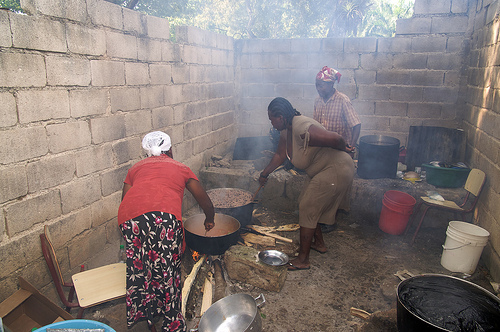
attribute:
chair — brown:
[406, 166, 486, 248]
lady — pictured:
[115, 127, 195, 292]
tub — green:
[414, 160, 476, 188]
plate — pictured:
[262, 249, 290, 269]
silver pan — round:
[259, 245, 290, 266]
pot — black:
[375, 260, 496, 327]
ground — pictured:
[302, 278, 335, 314]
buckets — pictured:
[361, 178, 496, 288]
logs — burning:
[187, 255, 232, 322]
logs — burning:
[223, 222, 297, 292]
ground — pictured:
[290, 266, 352, 326]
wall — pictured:
[53, 28, 120, 190]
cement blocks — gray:
[28, 59, 93, 144]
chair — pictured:
[32, 192, 144, 318]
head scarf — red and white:
[316, 63, 341, 85]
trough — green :
[408, 161, 481, 191]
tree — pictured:
[223, 1, 383, 29]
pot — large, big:
[199, 180, 257, 231]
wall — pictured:
[2, 14, 256, 120]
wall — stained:
[1, 1, 237, 312]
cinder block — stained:
[17, 86, 71, 125]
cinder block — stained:
[65, 19, 107, 56]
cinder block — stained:
[60, 173, 102, 215]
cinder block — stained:
[90, 113, 125, 146]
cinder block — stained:
[4, 186, 62, 237]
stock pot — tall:
[353, 129, 406, 180]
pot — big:
[176, 205, 243, 264]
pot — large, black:
[178, 206, 247, 262]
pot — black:
[356, 132, 403, 181]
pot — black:
[196, 183, 259, 237]